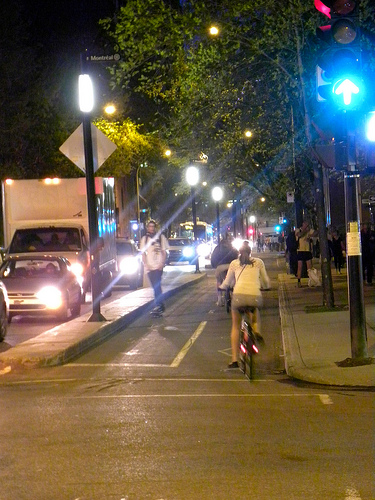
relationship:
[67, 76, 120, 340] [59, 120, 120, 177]
post on sign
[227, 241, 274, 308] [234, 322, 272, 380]
woman on bike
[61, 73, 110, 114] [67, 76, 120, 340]
light on post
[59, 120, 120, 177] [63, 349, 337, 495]
sign near road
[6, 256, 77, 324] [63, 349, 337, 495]
car on road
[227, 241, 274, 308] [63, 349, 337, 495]
woman in road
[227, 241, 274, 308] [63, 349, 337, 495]
woman on road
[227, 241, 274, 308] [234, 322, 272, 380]
woman riding bike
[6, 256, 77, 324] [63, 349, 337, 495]
car in road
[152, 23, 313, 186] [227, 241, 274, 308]
tree near woman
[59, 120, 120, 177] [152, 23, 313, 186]
sign near tree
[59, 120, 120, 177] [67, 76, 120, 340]
sign on post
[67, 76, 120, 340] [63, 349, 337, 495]
post on road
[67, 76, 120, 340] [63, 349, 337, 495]
post in road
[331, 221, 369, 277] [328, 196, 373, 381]
paper sign taped on pole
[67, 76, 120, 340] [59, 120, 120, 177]
post has sign